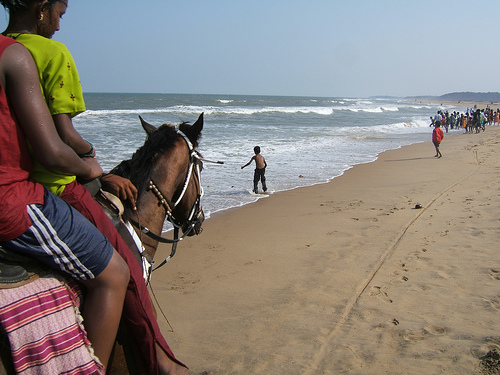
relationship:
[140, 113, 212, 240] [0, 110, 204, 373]
head of horse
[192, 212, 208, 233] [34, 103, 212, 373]
nose of horse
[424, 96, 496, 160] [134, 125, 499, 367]
people standing on beach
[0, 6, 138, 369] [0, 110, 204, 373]
people riding horse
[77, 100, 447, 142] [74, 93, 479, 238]
waves in ocean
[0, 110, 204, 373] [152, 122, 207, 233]
horse wearing bridle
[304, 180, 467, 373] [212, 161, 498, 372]
tracks in sand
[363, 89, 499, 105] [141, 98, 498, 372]
hills overlooking ocean beach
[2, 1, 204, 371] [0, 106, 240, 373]
girl on horse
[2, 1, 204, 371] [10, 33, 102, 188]
girl wearing shirt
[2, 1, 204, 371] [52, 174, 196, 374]
girl wearing pants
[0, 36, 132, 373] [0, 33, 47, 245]
boy wearing tank top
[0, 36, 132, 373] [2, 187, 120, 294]
boy wearing blue shorts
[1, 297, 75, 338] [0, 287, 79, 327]
blanket has stripe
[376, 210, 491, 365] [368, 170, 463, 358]
sand has footprints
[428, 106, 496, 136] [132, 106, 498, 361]
people are on beach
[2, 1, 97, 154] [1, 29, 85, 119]
person wears shirt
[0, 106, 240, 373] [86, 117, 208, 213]
horse has mane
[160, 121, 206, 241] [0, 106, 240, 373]
harness on horse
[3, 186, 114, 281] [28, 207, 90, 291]
shorts have stripe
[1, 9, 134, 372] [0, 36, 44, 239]
person wears shirt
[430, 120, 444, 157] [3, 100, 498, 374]
people are on beach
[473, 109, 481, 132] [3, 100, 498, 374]
people are on beach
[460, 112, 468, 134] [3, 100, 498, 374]
people are on beach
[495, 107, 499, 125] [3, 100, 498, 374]
people are on beach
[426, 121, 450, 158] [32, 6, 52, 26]
woman wears earring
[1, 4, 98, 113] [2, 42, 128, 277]
woman in front of man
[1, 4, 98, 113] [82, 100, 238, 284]
woman on horse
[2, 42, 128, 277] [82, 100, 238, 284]
man on horse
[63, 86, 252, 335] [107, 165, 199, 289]
horse has harness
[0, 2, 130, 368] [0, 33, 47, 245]
man wears tank top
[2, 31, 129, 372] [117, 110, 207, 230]
person on horse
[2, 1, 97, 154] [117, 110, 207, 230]
person on horse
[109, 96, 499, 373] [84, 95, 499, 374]
sand on beach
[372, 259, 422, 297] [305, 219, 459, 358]
footprints are in sand